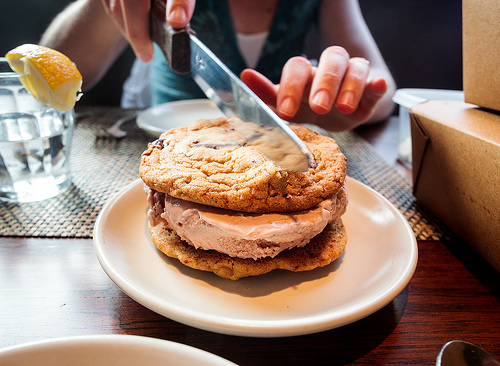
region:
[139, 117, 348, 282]
cookie ice cream sandwich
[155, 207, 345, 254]
ice cream between two cookies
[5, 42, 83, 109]
yellow lime slice on top of glass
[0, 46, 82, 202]
glass of water with lemon slice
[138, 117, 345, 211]
chocolate chip cookie on top of ice cream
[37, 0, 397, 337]
woman cutting an ice cream cookie sandwich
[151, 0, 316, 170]
metal blade knife with wooden handle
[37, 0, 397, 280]
woman cutting an ice cream sandwich on a white plate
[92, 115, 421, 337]
ice cream cookie sandwich served on a white plate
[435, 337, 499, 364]
tip of a stainless steel spoon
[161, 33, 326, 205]
a knife cutting a ice cream cookie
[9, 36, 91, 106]
slice of lemon on the glass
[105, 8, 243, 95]
girl holding the knife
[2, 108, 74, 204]
the glass is clear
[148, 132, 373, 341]
ice cream cookie on a plate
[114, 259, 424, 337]
the plate is white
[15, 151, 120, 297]
glass is on the placemat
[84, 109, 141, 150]
fork next to a plate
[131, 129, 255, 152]
chocolate chips in the cookie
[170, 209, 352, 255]
the ice cream is chocolate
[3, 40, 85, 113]
small lemon wedge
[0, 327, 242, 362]
partial view of a white plate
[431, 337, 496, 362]
partial view of a silver plated spoon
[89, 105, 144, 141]
silver plated fork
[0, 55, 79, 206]
small glass with water and ice in it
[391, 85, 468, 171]
partial view of a small container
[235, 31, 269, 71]
partial view of a woman's tank top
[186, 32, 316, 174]
long silver plated knife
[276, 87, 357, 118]
nicely manicured nails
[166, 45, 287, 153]
silver knife above food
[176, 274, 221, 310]
white plate under bun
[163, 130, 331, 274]
brown desvert on plate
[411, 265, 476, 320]
brown table below plate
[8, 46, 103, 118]
lemon in drink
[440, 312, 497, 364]
silver spoon on table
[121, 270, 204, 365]
two white plates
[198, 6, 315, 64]
shirt of the woman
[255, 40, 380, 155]
hand of the lady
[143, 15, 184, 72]
brown handle of the silver knife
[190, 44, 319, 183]
silver butter knife cutting cookes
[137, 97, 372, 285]
two cookies with ice cream in between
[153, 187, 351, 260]
chocolate ice cream between cookies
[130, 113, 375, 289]
ice cream sandwich on white plate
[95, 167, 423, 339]
white plate on brown table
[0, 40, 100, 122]
lemon wedge on rim of cup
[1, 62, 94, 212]
clear cup with water inside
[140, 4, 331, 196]
silver butter knife with wooden handle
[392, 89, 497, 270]
cardboard box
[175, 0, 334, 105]
white undershirt